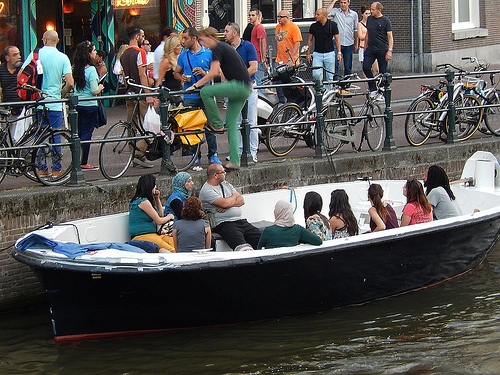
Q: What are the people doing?
A: Boat watching.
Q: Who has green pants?
A: Man climbing fence.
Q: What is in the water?
A: Boat.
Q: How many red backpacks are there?
A: 1.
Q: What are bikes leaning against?
A: Railing.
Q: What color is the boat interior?
A: White.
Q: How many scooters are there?
A: 1.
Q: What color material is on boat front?
A: Blue.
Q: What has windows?
A: Buildings.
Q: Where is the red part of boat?
A: In water.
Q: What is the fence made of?
A: Metal.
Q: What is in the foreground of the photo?
A: A boat.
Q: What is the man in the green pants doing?
A: Climbing the fence.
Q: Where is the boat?
A: In the water.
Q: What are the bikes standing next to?
A: A fence.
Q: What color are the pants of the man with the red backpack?
A: Blue.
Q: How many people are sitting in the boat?
A: Ten.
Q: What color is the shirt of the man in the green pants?
A: Black.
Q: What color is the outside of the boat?
A: Black.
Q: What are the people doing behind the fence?
A: Walking.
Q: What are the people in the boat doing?
A: Sitting.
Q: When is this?
A: Daytime.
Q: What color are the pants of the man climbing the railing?
A: Green.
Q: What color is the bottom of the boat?
A: Black.